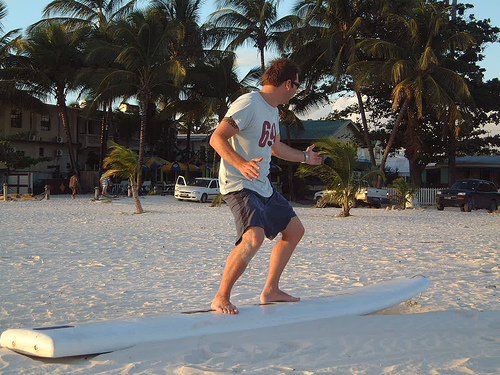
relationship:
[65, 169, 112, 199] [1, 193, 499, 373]
people on beach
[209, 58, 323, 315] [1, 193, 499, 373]
man on beach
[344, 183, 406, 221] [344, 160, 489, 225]
lights on truck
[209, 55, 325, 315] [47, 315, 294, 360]
man standing on surfboard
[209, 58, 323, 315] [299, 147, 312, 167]
man wearing watch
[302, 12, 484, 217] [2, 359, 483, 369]
trees border sand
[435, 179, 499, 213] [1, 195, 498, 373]
car on sand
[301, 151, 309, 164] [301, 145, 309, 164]
watch on wrist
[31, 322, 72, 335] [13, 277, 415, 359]
design on surfboard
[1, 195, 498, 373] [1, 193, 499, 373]
sand on beach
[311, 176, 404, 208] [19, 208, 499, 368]
truck parked on sand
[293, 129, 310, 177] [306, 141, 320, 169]
watch on hand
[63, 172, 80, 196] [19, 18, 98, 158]
person walking under tree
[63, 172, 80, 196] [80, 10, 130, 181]
person walking under tree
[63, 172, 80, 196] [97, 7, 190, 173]
person walking under tree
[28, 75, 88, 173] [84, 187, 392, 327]
house faces beach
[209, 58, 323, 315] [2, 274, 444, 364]
man on a surfboard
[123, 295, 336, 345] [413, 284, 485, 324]
surfboard in sand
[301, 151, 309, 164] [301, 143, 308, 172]
watch on wrist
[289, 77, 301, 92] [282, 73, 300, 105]
sunglasses on face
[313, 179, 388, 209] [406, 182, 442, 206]
truck next to fence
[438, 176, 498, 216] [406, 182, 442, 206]
car next to fence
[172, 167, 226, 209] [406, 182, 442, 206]
car next to fence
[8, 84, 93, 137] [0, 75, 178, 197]
roof on building